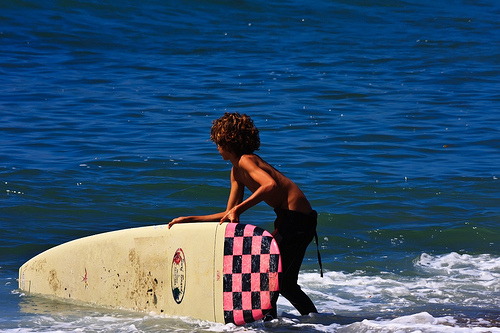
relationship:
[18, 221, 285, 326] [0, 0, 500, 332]
board in ocean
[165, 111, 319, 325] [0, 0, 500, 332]
boy in ocean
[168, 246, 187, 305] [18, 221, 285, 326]
logo on board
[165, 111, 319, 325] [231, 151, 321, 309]
boy has wetsuit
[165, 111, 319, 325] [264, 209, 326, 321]
boy has black pants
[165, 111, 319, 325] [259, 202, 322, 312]
boy wearing pants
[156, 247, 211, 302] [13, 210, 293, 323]
circle on board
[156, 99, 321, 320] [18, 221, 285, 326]
boy taking board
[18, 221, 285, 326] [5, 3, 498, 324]
board in water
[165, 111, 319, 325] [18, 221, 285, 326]
boy holding board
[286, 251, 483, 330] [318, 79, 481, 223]
foam in water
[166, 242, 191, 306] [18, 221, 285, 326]
logo on board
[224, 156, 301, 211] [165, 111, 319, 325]
torso on boy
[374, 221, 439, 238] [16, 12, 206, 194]
ripple in ocean water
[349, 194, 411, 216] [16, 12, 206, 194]
ripple in ocean water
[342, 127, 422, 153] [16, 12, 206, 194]
ripple in ocean water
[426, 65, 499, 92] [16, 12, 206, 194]
ripple in ocean water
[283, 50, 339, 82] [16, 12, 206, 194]
ripple in ocean water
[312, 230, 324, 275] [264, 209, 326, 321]
drawstring on black pants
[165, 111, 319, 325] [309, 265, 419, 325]
boy standing in water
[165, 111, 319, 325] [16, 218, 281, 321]
boy holding surf board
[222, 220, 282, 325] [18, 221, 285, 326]
end on board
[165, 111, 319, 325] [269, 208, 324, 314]
boy wearing pants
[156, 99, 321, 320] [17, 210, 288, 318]
boy with surfboard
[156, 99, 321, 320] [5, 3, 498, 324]
boy standing in water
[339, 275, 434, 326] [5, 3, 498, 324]
froth in water